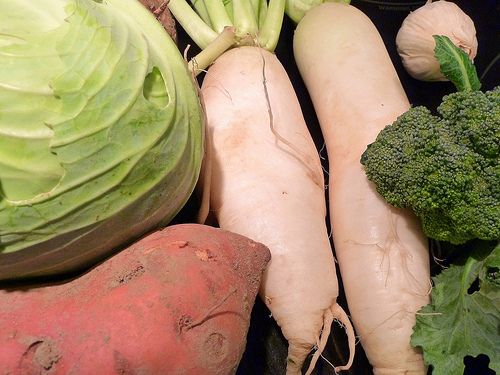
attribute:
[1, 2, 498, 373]
vegetables — different, close to each other, various, a pile, in a pile, a variety, healthy, a few, colorful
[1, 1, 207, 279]
leaf — bug-eaten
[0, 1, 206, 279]
cabbage — green, a head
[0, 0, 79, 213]
curved edge — torn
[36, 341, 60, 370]
dirt — brown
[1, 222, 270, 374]
sweet potato — red-skinned, large, a corner, dirty, red skinned, dirt covered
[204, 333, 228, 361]
marking — circular, small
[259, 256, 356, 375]
bottom — pointy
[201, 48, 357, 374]
turnip — white, pale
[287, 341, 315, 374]
root — thick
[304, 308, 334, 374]
root — thin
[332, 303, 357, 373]
root — thin, sticking out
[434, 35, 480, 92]
leaf — small, single, green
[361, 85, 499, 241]
broccoli — green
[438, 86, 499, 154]
floret — with dirt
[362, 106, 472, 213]
floret — with dirt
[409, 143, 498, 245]
floret — with dirt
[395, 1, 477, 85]
garlic — a head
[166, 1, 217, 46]
stalk — light-green, green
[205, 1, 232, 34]
stalk — light-green, green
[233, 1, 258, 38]
stalk — light-green, green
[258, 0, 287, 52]
stalk — light-green, green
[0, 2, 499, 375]
table — black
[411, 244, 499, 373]
leaf — large, dry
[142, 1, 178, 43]
vegetable — brown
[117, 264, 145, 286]
spot — black, small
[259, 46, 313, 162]
string — tiny, a piece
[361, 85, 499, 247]
spores — small